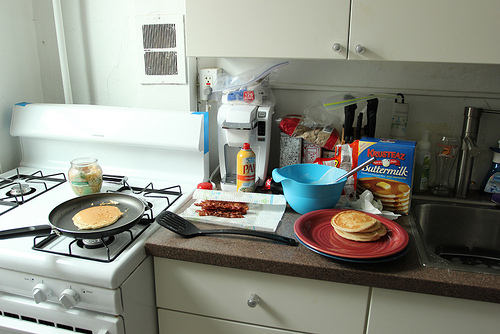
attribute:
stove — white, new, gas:
[3, 103, 202, 332]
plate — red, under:
[293, 207, 411, 259]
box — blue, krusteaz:
[352, 139, 416, 217]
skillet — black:
[0, 191, 146, 251]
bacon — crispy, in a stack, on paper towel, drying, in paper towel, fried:
[193, 201, 250, 218]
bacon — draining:
[177, 189, 290, 234]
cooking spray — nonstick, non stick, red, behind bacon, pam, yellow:
[236, 144, 256, 193]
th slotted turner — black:
[154, 208, 298, 259]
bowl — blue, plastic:
[272, 163, 347, 217]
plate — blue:
[290, 221, 410, 263]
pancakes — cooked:
[71, 204, 122, 231]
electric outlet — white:
[198, 69, 217, 97]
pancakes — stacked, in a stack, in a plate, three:
[330, 208, 389, 242]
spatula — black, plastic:
[156, 210, 299, 239]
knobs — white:
[30, 285, 81, 311]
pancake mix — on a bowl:
[271, 163, 351, 215]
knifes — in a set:
[340, 96, 380, 148]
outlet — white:
[192, 68, 220, 102]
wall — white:
[49, 1, 193, 114]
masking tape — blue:
[190, 111, 208, 153]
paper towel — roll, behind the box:
[389, 93, 409, 143]